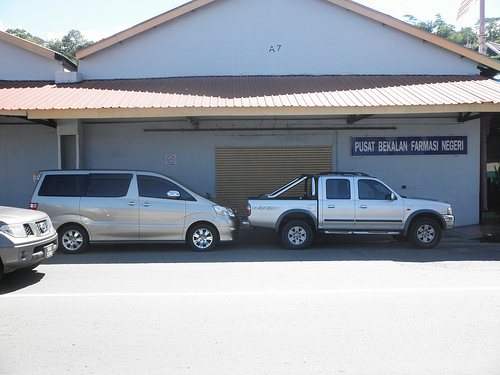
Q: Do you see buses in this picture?
A: No, there are no buses.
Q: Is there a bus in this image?
A: No, there are no buses.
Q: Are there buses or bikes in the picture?
A: No, there are no buses or bikes.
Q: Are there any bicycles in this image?
A: No, there are no bicycles.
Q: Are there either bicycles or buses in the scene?
A: No, there are no bicycles or buses.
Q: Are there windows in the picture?
A: Yes, there is a window.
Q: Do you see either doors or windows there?
A: Yes, there is a window.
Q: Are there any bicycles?
A: No, there are no bicycles.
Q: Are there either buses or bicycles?
A: No, there are no bicycles or buses.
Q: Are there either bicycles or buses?
A: No, there are no bicycles or buses.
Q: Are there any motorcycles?
A: No, there are no motorcycles.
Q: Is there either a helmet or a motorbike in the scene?
A: No, there are no motorcycles or helmets.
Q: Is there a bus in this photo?
A: No, there are no buses.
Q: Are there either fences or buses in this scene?
A: No, there are no buses or fences.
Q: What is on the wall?
A: The sign is on the wall.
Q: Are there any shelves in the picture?
A: No, there are no shelves.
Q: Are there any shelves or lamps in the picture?
A: No, there are no shelves or lamps.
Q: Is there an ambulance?
A: No, there are no ambulances.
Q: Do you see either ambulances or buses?
A: No, there are no ambulances or buses.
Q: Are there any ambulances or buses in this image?
A: No, there are no ambulances or buses.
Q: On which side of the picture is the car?
A: The car is on the left of the image.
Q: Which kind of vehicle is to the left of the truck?
A: The vehicle is a car.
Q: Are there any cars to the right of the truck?
A: No, the car is to the left of the truck.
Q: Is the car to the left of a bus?
A: No, the car is to the left of a truck.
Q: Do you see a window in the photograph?
A: Yes, there is a window.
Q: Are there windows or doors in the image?
A: Yes, there is a window.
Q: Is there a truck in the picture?
A: Yes, there is a truck.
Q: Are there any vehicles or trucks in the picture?
A: Yes, there is a truck.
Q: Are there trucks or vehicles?
A: Yes, there is a truck.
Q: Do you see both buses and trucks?
A: No, there is a truck but no buses.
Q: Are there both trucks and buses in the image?
A: No, there is a truck but no buses.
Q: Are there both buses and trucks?
A: No, there is a truck but no buses.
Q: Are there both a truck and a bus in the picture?
A: No, there is a truck but no buses.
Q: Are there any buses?
A: No, there are no buses.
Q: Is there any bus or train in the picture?
A: No, there are no buses or trains.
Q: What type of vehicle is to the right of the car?
A: The vehicle is a truck.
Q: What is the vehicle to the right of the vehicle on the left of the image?
A: The vehicle is a truck.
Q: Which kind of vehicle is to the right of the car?
A: The vehicle is a truck.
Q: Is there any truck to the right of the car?
A: Yes, there is a truck to the right of the car.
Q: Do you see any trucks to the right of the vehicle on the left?
A: Yes, there is a truck to the right of the car.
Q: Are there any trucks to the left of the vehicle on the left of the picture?
A: No, the truck is to the right of the car.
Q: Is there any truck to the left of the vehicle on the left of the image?
A: No, the truck is to the right of the car.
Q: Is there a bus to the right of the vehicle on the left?
A: No, there is a truck to the right of the car.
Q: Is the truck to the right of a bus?
A: No, the truck is to the right of a car.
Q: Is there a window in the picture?
A: Yes, there is a window.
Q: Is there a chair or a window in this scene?
A: Yes, there is a window.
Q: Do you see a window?
A: Yes, there is a window.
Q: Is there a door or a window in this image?
A: Yes, there is a window.